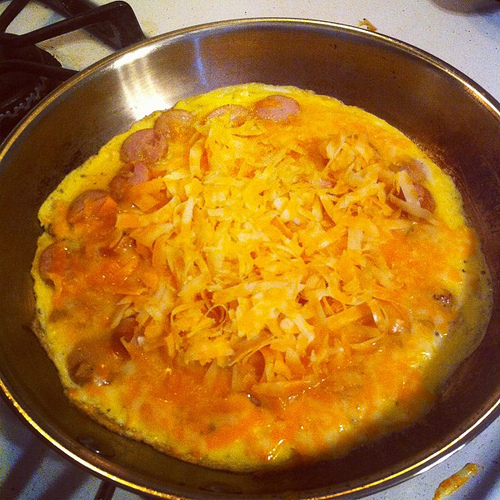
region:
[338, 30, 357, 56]
Gray pan that omelet is being cooked on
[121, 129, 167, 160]
Sausage in the omelet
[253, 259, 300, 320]
Small patch of cheese in the omelet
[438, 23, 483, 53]
White part of the stove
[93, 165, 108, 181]
Small part of the yolk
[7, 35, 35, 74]
Black burner on the stove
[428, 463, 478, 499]
Part of the omelet on the stove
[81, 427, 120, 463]
Circular object on the pan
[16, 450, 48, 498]
Shadow of the pot seen on the stove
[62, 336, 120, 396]
Sausage melted in the omelet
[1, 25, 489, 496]
egg dish in skillet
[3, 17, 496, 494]
egg dish in frying pan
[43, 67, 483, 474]
egg scramble with sausage and cheese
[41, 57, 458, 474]
scrambled eggs with sausage and cheese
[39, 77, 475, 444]
sausage and cheese omelet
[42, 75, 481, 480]
omelet with sausage and cheese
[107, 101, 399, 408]
shredded cheese on top of eggs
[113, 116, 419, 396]
cheese grated on top of omelet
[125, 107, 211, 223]
sliced sausage in eggs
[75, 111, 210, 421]
sliced hot dog in eggs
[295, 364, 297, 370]
par tof a food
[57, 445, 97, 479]
edge of a an edge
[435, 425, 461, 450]
part of an edge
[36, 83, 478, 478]
the food is on a skillet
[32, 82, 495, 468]
the meal is an omelet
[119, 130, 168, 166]
the meal has meat slices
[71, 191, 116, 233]
the meat is cut into circles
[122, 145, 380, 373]
pasta is on the omelet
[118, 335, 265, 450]
the omelet has an orange ingredient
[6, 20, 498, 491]
the skillet is made of metal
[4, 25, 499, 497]
the skillet is shiny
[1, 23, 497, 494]
the skillet is made of steel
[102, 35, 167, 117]
a highlight is on the skillet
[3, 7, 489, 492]
round silver pan on top of stove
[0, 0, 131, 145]
black metal support over burner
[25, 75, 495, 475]
bright yellow omelet spread over bottom of pan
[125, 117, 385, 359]
yellow shredded cheese over omelet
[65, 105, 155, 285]
round slices of brown sausage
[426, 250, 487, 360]
small dark bubbles on edge of eggs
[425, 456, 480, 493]
shred of cheese melting on stove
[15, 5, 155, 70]
yellow stains on stove top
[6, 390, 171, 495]
brown residue on silver edge of pan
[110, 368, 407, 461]
melted orange cheese on edge of omelet